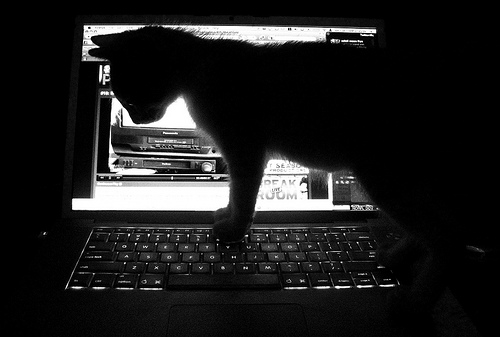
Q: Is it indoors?
A: Yes, it is indoors.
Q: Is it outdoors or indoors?
A: It is indoors.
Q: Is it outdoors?
A: No, it is indoors.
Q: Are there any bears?
A: No, there are no bears.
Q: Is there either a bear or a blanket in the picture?
A: No, there are no bears or blankets.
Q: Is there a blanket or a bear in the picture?
A: No, there are no bears or blankets.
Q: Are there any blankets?
A: No, there are no blankets.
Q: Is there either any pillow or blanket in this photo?
A: No, there are no blankets or pillows.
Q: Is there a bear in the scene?
A: No, there are no bears.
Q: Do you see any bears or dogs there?
A: No, there are no bears or dogs.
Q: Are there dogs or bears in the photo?
A: No, there are no bears or dogs.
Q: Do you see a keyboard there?
A: Yes, there is a keyboard.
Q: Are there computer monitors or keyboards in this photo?
A: Yes, there is a keyboard.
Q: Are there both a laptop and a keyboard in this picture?
A: Yes, there are both a keyboard and a laptop.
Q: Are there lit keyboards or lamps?
A: Yes, there is a lit keyboard.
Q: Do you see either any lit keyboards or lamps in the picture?
A: Yes, there is a lit keyboard.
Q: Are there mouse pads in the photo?
A: No, there are no mouse pads.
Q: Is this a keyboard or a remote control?
A: This is a keyboard.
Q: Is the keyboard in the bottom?
A: Yes, the keyboard is in the bottom of the image.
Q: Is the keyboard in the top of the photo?
A: No, the keyboard is in the bottom of the image.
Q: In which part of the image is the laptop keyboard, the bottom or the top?
A: The keyboard is in the bottom of the image.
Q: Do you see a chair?
A: No, there are no chairs.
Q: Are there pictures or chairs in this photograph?
A: No, there are no chairs or pictures.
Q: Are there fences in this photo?
A: No, there are no fences.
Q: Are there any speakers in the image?
A: No, there are no speakers.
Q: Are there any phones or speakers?
A: No, there are no speakers or phones.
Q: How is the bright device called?
A: The device is a screen.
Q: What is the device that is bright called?
A: The device is a screen.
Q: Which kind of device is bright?
A: The device is a screen.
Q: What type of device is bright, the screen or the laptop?
A: The screen is bright.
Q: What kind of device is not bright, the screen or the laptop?
A: The laptop is not bright.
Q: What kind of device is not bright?
A: The device is a laptop.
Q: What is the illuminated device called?
A: The device is a screen.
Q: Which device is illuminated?
A: The device is a screen.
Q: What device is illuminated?
A: The device is a screen.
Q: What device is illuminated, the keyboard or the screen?
A: The screen is illuminated.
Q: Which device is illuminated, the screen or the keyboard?
A: The screen is illuminated.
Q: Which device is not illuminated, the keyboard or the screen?
A: The keyboard is not illuminated.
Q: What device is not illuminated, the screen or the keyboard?
A: The keyboard is not illuminated.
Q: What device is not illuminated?
A: The device is a keyboard.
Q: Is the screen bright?
A: Yes, the screen is bright.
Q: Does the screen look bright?
A: Yes, the screen is bright.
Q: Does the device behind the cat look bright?
A: Yes, the screen is bright.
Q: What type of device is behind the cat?
A: The device is a screen.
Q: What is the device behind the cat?
A: The device is a screen.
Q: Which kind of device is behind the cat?
A: The device is a screen.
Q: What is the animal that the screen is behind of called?
A: The animal is a cat.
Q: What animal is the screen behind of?
A: The screen is behind the cat.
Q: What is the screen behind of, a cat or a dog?
A: The screen is behind a cat.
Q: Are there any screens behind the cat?
A: Yes, there is a screen behind the cat.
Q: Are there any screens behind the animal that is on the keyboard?
A: Yes, there is a screen behind the cat.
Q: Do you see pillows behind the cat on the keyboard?
A: No, there is a screen behind the cat.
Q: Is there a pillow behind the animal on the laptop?
A: No, there is a screen behind the cat.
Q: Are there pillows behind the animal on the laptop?
A: No, there is a screen behind the cat.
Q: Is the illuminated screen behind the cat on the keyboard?
A: Yes, the screen is behind the cat.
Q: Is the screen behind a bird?
A: No, the screen is behind the cat.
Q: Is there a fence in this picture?
A: No, there are no fences.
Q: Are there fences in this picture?
A: No, there are no fences.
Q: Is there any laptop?
A: Yes, there is a laptop.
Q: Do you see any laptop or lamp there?
A: Yes, there is a laptop.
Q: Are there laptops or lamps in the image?
A: Yes, there is a laptop.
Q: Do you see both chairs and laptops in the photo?
A: No, there is a laptop but no chairs.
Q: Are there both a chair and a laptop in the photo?
A: No, there is a laptop but no chairs.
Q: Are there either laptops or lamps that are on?
A: Yes, the laptop is on.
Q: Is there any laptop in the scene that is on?
A: Yes, there is a laptop that is on.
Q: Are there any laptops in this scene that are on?
A: Yes, there is a laptop that is on.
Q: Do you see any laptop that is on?
A: Yes, there is a laptop that is on.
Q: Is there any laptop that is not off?
A: Yes, there is a laptop that is on.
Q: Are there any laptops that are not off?
A: Yes, there is a laptop that is on.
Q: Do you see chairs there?
A: No, there are no chairs.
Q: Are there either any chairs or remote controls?
A: No, there are no chairs or remote controls.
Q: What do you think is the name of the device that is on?
A: The device is a laptop.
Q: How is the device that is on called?
A: The device is a laptop.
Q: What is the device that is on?
A: The device is a laptop.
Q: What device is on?
A: The device is a laptop.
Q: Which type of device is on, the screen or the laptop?
A: The laptop is on.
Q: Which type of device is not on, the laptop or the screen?
A: The screen is not on.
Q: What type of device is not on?
A: The device is a screen.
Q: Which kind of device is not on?
A: The device is a screen.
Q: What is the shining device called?
A: The device is a laptop.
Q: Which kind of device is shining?
A: The device is a laptop.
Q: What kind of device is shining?
A: The device is a laptop.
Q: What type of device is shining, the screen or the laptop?
A: The laptop is shining.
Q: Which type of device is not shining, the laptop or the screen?
A: The screen is not shining.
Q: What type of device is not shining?
A: The device is a screen.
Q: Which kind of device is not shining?
A: The device is a screen.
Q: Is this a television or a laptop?
A: This is a laptop.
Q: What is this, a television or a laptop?
A: This is a laptop.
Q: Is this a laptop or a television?
A: This is a laptop.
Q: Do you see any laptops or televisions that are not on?
A: No, there is a laptop but it is on.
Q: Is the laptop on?
A: Yes, the laptop is on.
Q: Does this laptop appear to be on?
A: Yes, the laptop is on.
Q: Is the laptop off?
A: No, the laptop is on.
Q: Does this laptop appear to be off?
A: No, the laptop is on.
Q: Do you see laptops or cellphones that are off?
A: No, there is a laptop but it is on.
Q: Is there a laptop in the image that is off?
A: No, there is a laptop but it is on.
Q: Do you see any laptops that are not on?
A: No, there is a laptop but it is on.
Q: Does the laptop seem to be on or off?
A: The laptop is on.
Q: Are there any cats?
A: Yes, there is a cat.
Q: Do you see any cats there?
A: Yes, there is a cat.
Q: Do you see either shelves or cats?
A: Yes, there is a cat.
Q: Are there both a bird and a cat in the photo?
A: No, there is a cat but no birds.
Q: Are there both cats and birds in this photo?
A: No, there is a cat but no birds.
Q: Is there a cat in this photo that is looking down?
A: Yes, there is a cat that is looking down.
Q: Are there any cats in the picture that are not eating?
A: Yes, there is a cat that is looking down.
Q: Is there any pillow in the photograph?
A: No, there are no pillows.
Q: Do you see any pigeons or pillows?
A: No, there are no pillows or pigeons.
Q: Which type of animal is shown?
A: The animal is a cat.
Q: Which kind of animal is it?
A: The animal is a cat.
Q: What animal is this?
A: This is a cat.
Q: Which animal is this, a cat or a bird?
A: This is a cat.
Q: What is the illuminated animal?
A: The animal is a cat.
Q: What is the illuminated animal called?
A: The animal is a cat.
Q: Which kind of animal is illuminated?
A: The animal is a cat.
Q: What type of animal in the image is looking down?
A: The animal is a cat.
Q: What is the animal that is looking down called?
A: The animal is a cat.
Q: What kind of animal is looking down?
A: The animal is a cat.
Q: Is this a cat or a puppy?
A: This is a cat.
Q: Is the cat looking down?
A: Yes, the cat is looking down.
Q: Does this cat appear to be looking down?
A: Yes, the cat is looking down.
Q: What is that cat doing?
A: The cat is looking down.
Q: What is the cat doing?
A: The cat is looking down.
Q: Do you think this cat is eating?
A: No, the cat is looking down.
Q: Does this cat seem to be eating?
A: No, the cat is looking down.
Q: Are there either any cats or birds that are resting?
A: No, there is a cat but it is looking down.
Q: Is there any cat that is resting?
A: No, there is a cat but it is looking down.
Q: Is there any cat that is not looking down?
A: No, there is a cat but it is looking down.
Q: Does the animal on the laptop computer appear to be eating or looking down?
A: The cat is looking down.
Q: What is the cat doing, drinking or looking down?
A: The cat is looking down.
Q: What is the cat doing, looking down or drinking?
A: The cat is looking down.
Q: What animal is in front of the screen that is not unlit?
A: The cat is in front of the screen.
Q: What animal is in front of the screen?
A: The cat is in front of the screen.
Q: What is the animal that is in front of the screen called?
A: The animal is a cat.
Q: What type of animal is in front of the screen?
A: The animal is a cat.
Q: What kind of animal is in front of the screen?
A: The animal is a cat.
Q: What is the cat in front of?
A: The cat is in front of the screen.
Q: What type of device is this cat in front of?
A: The cat is in front of the screen.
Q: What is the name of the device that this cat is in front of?
A: The device is a screen.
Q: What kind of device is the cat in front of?
A: The cat is in front of the screen.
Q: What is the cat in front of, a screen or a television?
A: The cat is in front of a screen.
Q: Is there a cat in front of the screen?
A: Yes, there is a cat in front of the screen.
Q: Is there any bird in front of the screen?
A: No, there is a cat in front of the screen.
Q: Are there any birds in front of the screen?
A: No, there is a cat in front of the screen.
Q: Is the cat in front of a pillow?
A: No, the cat is in front of a screen.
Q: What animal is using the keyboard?
A: The cat is using the keyboard.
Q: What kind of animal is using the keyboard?
A: The animal is a cat.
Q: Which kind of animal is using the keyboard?
A: The animal is a cat.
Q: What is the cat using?
A: The cat is using a keyboard.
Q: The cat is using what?
A: The cat is using a keyboard.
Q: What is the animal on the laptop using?
A: The cat is using a keyboard.